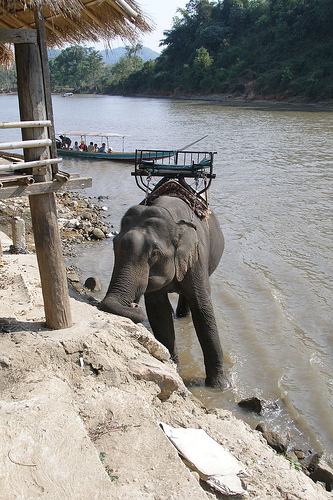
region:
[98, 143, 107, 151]
person sitting on boat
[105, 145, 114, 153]
person sitting on boat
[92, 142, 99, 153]
person sitting on boat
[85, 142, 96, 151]
person sitting on boat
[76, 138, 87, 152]
person sitting on boat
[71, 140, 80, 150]
person sitting on boat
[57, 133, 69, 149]
person sitting on boat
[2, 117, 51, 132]
light wooden porch rail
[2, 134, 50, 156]
light wooden porch rail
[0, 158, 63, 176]
light wooden porch rail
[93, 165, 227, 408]
an elephant is next to thj water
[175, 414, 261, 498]
a white cloth on the floor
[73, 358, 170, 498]
the floor is gray in color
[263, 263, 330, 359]
water is colorles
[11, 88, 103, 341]
the syal is made of wood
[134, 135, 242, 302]
elep[hant has a carir at the back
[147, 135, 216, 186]
the carier is mad of metal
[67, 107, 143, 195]
a boatis i water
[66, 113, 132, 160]
the boat is blue in color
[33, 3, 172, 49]
the stall is grass tatched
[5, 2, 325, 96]
mountain behind trees and plant-covered slope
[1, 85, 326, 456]
river used by people and elephants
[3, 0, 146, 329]
grass-covered roof on elevated terrace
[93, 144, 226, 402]
gray elephant with empty bench strapped on back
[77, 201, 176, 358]
elephant using trunk to push against rock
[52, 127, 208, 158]
screen on poles sheltering people on boat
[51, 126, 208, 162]
people riding narrow boat with a curving front tip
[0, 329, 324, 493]
rough steps leading down to water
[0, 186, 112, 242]
flat rocks in dirt mound by water's edge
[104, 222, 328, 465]
rippling water on elephant's side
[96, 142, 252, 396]
an elephant in the water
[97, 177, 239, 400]
the elephant is color gray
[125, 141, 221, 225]
a bench on an elephant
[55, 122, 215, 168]
a boat in the river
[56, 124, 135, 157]
the boat has a roof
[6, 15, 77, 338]
a pole is color brown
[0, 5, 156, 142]
the roof is made of straw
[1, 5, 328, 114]
green plants behind the water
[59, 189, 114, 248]
pebbles on the river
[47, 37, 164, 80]
a mountain on the background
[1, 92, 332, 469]
a large brown body of water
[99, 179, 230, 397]
elephant standing in the water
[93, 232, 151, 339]
elephant's trunk is curled on the edge of the bank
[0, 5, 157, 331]
thick post holding up partially visible structure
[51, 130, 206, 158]
large section of a long boat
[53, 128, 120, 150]
boat has a roof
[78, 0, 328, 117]
wooded hill on far side of water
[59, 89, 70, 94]
boat in the distance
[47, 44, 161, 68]
low hills in distance have a faded blue appearance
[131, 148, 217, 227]
chair fixed onto elephant's back